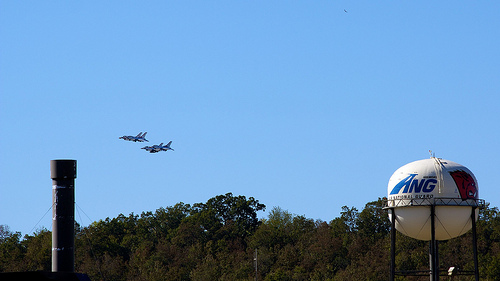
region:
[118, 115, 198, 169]
fighter jets flying overhead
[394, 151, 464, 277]
water tower in a town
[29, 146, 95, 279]
metal cylindrical chimney of a factory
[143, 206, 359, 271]
the top of several green trees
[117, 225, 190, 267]
thousands of green leaves on trees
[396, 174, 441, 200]
blue letter on a water tower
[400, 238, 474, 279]
black metal supports on water tower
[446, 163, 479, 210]
red wolf painted on water tower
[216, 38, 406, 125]
clear blue sky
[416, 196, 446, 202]
bridge around water tower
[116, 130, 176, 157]
two planes in the blue sky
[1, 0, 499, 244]
clear blue sky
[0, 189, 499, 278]
green trees in the background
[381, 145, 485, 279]
white colored water tower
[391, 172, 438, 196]
blue letters on the white water tower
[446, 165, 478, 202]
logo of a red animal on the water tower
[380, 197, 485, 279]
black metal beams holding the water reservoir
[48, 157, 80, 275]
large metal black pipe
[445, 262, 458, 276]
white box item on the beams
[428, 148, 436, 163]
highest point on the water tower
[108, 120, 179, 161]
Planes in the sky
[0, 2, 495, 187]
Sky is blue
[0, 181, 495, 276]
Trees with green leaves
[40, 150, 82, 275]
Tower is brown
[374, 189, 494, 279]
Black structure holding a glove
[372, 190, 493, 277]
Structure is black is big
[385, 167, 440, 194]
Words says Ang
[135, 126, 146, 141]
Tail of plane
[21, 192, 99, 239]
Strings in tower on sides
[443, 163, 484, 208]
Red spot on glove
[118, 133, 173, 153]
Four jets flying through the sky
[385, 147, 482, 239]
The top of a water tower that says ANG on it real big.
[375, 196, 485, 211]
Metal railing around a water tower.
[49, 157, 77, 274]
Large black stack coming from a building.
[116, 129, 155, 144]
First two jets in sequence.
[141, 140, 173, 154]
Last two jets in sequence.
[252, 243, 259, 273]
Pole sticking out in the middle of a lot of trees.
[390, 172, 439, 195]
Blue letters that say ANG on a water tower.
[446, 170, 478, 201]
Picture of a red animal on the side of a water tower.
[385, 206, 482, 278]
Large black metal support poles for a water tower.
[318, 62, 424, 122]
part of the sky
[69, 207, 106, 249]
part of some wires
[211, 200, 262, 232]
top of some trees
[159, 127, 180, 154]
part of a tail wing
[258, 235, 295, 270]
part of some tree branches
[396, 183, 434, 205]
part of a balcony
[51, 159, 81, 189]
edge of the post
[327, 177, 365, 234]
part of a tree branch